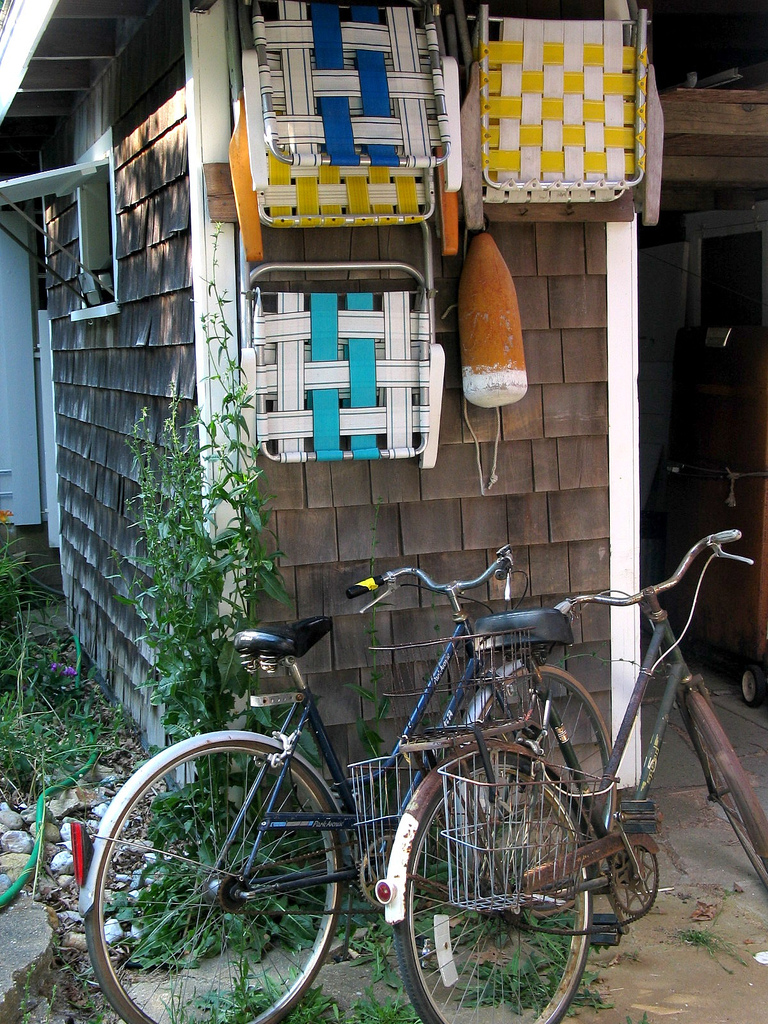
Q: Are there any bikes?
A: Yes, there is a bike.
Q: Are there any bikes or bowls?
A: Yes, there is a bike.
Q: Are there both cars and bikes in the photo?
A: No, there is a bike but no cars.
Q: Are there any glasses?
A: No, there are no glasses.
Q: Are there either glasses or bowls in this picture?
A: No, there are no glasses or bowls.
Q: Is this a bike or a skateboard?
A: This is a bike.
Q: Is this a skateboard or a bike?
A: This is a bike.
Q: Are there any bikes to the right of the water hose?
A: Yes, there is a bike to the right of the water hose.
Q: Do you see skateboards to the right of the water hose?
A: No, there is a bike to the right of the water hose.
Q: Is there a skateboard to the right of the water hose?
A: No, there is a bike to the right of the water hose.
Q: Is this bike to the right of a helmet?
A: No, the bike is to the right of a hose.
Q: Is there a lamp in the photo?
A: No, there are no lamps.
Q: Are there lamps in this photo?
A: No, there are no lamps.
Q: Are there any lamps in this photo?
A: No, there are no lamps.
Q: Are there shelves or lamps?
A: No, there are no lamps or shelves.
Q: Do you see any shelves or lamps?
A: No, there are no lamps or shelves.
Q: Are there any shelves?
A: No, there are no shelves.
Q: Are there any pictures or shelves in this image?
A: No, there are no shelves or pictures.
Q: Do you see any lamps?
A: No, there are no lamps.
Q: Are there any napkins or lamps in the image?
A: No, there are no lamps or napkins.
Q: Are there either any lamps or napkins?
A: No, there are no lamps or napkins.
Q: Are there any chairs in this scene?
A: Yes, there is a chair.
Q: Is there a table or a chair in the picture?
A: Yes, there is a chair.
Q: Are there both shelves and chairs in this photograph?
A: No, there is a chair but no shelves.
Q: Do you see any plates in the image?
A: No, there are no plates.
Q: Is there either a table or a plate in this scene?
A: No, there are no plates or tables.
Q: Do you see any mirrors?
A: No, there are no mirrors.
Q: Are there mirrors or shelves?
A: No, there are no mirrors or shelves.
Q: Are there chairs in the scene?
A: Yes, there is a chair.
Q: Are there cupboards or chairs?
A: Yes, there is a chair.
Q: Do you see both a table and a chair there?
A: No, there is a chair but no tables.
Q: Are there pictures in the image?
A: No, there are no pictures.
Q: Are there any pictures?
A: No, there are no pictures.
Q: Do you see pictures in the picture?
A: No, there are no pictures.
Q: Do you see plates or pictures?
A: No, there are no pictures or plates.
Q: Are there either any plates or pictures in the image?
A: No, there are no pictures or plates.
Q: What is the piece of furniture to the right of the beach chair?
A: The piece of furniture is a chair.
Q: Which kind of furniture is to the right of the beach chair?
A: The piece of furniture is a chair.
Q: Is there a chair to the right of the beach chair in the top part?
A: Yes, there is a chair to the right of the beach chair.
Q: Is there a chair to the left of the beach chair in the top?
A: No, the chair is to the right of the beach chair.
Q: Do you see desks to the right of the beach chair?
A: No, there is a chair to the right of the beach chair.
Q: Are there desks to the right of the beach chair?
A: No, there is a chair to the right of the beach chair.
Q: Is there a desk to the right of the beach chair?
A: No, there is a chair to the right of the beach chair.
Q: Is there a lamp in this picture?
A: No, there are no lamps.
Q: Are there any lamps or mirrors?
A: No, there are no lamps or mirrors.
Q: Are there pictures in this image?
A: No, there are no pictures.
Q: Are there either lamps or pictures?
A: No, there are no pictures or lamps.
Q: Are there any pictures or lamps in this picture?
A: No, there are no pictures or lamps.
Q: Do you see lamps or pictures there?
A: No, there are no pictures or lamps.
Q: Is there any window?
A: Yes, there is a window.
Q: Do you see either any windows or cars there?
A: Yes, there is a window.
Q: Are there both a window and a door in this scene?
A: No, there is a window but no doors.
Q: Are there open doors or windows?
A: Yes, there is an open window.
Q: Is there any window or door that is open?
A: Yes, the window is open.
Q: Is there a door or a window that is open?
A: Yes, the window is open.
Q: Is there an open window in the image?
A: Yes, there is an open window.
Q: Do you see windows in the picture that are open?
A: Yes, there is an open window.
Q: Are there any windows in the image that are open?
A: Yes, there is a window that is open.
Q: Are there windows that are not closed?
A: Yes, there is a open window.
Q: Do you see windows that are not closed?
A: Yes, there is a open window.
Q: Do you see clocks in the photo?
A: No, there are no clocks.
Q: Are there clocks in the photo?
A: No, there are no clocks.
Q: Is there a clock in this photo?
A: No, there are no clocks.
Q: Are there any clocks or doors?
A: No, there are no clocks or doors.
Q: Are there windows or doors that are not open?
A: No, there is a window but it is open.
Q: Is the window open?
A: Yes, the window is open.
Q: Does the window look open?
A: Yes, the window is open.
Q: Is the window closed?
A: No, the window is open.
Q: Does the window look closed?
A: No, the window is open.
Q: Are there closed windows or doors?
A: No, there is a window but it is open.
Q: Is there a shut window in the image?
A: No, there is a window but it is open.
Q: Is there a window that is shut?
A: No, there is a window but it is open.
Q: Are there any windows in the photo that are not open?
A: No, there is a window but it is open.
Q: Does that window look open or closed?
A: The window is open.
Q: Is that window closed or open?
A: The window is open.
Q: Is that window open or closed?
A: The window is open.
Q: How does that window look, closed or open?
A: The window is open.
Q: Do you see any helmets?
A: No, there are no helmets.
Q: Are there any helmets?
A: No, there are no helmets.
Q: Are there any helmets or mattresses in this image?
A: No, there are no helmets or mattresses.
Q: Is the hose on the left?
A: Yes, the hose is on the left of the image.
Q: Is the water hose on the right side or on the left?
A: The water hose is on the left of the image.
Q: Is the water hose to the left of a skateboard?
A: No, the water hose is to the left of the bike.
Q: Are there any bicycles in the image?
A: Yes, there is a bicycle.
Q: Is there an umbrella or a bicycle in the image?
A: Yes, there is a bicycle.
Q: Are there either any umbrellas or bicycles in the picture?
A: Yes, there is a bicycle.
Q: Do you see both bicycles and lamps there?
A: No, there is a bicycle but no lamps.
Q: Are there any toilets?
A: No, there are no toilets.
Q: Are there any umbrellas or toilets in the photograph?
A: No, there are no toilets or umbrellas.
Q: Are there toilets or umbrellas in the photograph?
A: No, there are no toilets or umbrellas.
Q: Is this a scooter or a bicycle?
A: This is a bicycle.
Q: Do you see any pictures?
A: No, there are no pictures.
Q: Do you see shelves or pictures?
A: No, there are no pictures or shelves.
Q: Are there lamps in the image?
A: No, there are no lamps.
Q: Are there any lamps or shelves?
A: No, there are no lamps or shelves.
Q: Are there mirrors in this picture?
A: No, there are no mirrors.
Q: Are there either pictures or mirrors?
A: No, there are no mirrors or pictures.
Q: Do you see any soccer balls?
A: No, there are no soccer balls.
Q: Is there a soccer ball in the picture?
A: No, there are no soccer balls.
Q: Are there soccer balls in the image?
A: No, there are no soccer balls.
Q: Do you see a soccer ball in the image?
A: No, there are no soccer balls.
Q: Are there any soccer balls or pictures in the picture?
A: No, there are no soccer balls or pictures.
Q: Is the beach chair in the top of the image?
A: Yes, the beach chair is in the top of the image.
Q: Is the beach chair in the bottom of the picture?
A: No, the beach chair is in the top of the image.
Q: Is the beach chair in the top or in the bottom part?
A: The beach chair is in the top of the image.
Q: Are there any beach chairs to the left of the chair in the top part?
A: Yes, there is a beach chair to the left of the chair.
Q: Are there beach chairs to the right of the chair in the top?
A: No, the beach chair is to the left of the chair.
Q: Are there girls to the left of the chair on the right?
A: No, there is a beach chair to the left of the chair.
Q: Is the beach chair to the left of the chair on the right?
A: Yes, the beach chair is to the left of the chair.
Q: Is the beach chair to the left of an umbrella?
A: No, the beach chair is to the left of the chair.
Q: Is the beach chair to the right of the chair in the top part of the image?
A: No, the beach chair is to the left of the chair.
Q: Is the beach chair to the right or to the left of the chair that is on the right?
A: The beach chair is to the left of the chair.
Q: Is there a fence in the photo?
A: No, there are no fences.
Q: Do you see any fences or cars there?
A: No, there are no fences or cars.